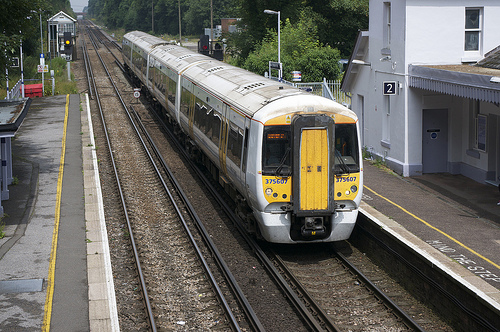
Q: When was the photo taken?
A: Daytime.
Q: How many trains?
A: One.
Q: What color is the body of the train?
A: White.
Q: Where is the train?
A: Track.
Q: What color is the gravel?
A: Gray.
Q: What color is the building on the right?
A: White.